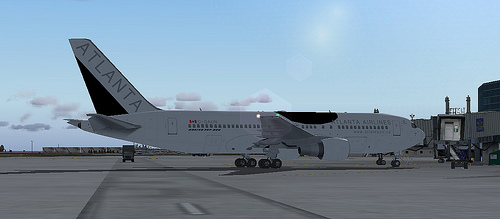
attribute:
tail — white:
[65, 37, 166, 149]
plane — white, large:
[64, 37, 429, 172]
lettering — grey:
[75, 40, 142, 113]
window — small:
[186, 122, 192, 127]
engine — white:
[296, 134, 353, 163]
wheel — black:
[392, 158, 401, 167]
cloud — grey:
[7, 122, 53, 134]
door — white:
[392, 119, 401, 139]